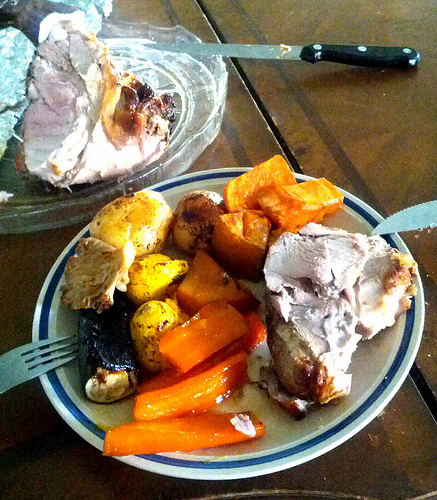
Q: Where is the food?
A: Plate.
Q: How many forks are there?
A: One.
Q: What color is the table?
A: Brown.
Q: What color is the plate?
A: White.